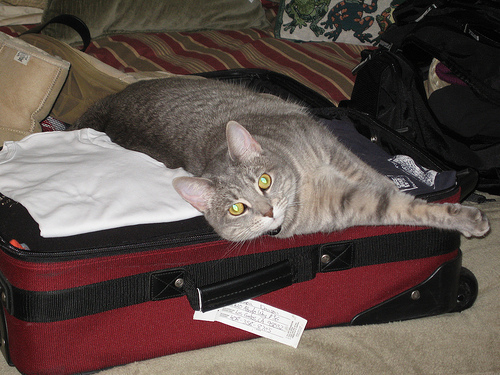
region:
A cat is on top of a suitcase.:
[43, 93, 455, 253]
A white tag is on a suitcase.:
[189, 284, 316, 355]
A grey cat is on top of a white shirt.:
[5, 129, 380, 245]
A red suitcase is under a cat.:
[26, 125, 498, 329]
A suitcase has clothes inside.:
[25, 107, 145, 304]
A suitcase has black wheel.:
[436, 251, 487, 321]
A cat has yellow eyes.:
[203, 168, 315, 231]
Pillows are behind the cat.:
[59, 0, 396, 50]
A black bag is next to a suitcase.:
[358, 13, 494, 172]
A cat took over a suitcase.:
[88, 74, 457, 274]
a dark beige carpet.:
[370, 330, 478, 368]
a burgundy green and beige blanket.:
[146, 30, 233, 60]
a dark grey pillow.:
[85, 0, 240, 25]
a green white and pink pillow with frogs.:
[270, 0, 385, 45]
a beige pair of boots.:
[0, 30, 85, 135]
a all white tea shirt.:
[52, 162, 117, 207]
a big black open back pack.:
[347, 0, 497, 192]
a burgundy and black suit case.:
[72, 251, 327, 314]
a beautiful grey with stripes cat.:
[67, 71, 491, 243]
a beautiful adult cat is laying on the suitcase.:
[0, 47, 499, 372]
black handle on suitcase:
[176, 265, 305, 303]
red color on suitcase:
[83, 324, 190, 355]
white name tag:
[182, 293, 318, 348]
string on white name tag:
[188, 283, 216, 315]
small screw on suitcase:
[407, 288, 427, 300]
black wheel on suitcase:
[451, 260, 488, 320]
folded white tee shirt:
[8, 123, 204, 225]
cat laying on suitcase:
[193, 117, 468, 264]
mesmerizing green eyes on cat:
[245, 166, 289, 193]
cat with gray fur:
[302, 131, 366, 206]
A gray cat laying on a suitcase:
[88, 77, 482, 251]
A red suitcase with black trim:
[3, 200, 471, 343]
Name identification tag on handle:
[187, 290, 319, 358]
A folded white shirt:
[5, 138, 146, 232]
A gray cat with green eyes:
[208, 148, 282, 229]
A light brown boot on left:
[6, 56, 71, 121]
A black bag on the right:
[355, 67, 482, 167]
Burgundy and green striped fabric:
[149, 28, 321, 66]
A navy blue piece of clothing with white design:
[328, 115, 435, 207]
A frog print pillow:
[275, 6, 370, 41]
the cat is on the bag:
[46, 53, 498, 301]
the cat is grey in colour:
[85, 68, 473, 260]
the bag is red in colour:
[64, 232, 336, 342]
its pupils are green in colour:
[164, 134, 360, 235]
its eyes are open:
[148, 108, 318, 258]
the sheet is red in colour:
[198, 22, 323, 65]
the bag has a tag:
[139, 228, 324, 373]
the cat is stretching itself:
[91, 56, 488, 278]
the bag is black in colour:
[363, 15, 488, 159]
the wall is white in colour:
[283, 0, 384, 52]